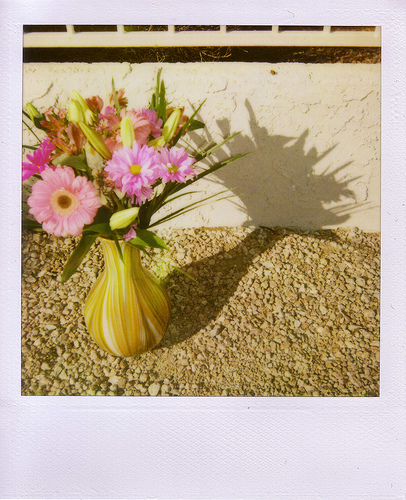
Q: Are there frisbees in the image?
A: No, there are no frisbees.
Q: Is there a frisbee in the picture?
A: No, there are no frisbees.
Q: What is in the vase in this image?
A: The flower is in the vase.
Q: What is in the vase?
A: The flower is in the vase.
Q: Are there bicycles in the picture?
A: No, there are no bicycles.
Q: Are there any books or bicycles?
A: No, there are no bicycles or books.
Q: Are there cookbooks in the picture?
A: No, there are no cookbooks.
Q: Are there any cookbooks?
A: No, there are no cookbooks.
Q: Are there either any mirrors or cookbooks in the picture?
A: No, there are no cookbooks or mirrors.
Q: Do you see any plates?
A: No, there are no plates.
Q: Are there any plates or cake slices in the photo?
A: No, there are no plates or cake slices.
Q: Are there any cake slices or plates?
A: No, there are no plates or cake slices.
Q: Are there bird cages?
A: No, there are no bird cages.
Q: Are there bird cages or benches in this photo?
A: No, there are no bird cages or benches.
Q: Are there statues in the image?
A: No, there are no statues.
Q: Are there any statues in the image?
A: No, there are no statues.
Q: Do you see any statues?
A: No, there are no statues.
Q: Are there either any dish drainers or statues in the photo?
A: No, there are no statues or dish drainers.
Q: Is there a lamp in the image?
A: No, there are no lamps.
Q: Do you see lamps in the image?
A: No, there are no lamps.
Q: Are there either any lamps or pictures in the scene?
A: No, there are no lamps or pictures.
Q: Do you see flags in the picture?
A: No, there are no flags.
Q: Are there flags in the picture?
A: No, there are no flags.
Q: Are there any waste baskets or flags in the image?
A: No, there are no flags or waste baskets.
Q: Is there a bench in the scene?
A: No, there are no benches.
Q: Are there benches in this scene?
A: No, there are no benches.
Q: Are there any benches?
A: No, there are no benches.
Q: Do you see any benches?
A: No, there are no benches.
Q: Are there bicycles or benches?
A: No, there are no benches or bicycles.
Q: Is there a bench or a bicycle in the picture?
A: No, there are no benches or bicycles.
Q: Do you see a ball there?
A: No, there are no balls.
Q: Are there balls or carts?
A: No, there are no balls or carts.